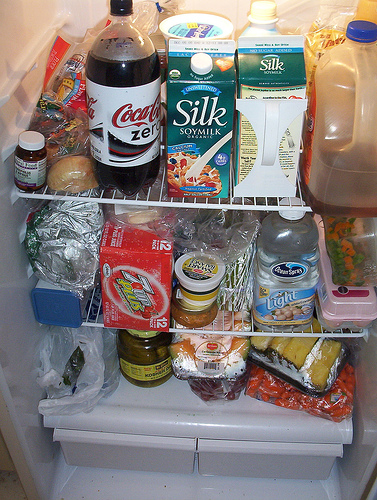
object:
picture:
[1, 0, 377, 497]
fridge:
[1, 0, 375, 497]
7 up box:
[95, 212, 176, 337]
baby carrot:
[336, 371, 355, 401]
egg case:
[311, 213, 375, 337]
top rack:
[4, 0, 376, 216]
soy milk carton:
[161, 33, 238, 208]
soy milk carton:
[233, 28, 306, 201]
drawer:
[48, 427, 199, 483]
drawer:
[195, 432, 348, 485]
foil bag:
[20, 195, 104, 299]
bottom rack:
[27, 324, 366, 449]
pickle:
[114, 327, 173, 391]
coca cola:
[82, 0, 164, 197]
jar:
[114, 327, 169, 390]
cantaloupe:
[168, 332, 250, 381]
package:
[169, 331, 254, 378]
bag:
[243, 361, 357, 426]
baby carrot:
[270, 385, 285, 407]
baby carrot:
[256, 388, 274, 405]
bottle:
[11, 127, 50, 197]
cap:
[16, 128, 46, 153]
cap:
[106, 0, 135, 16]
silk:
[172, 90, 233, 131]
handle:
[49, 428, 200, 454]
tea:
[299, 163, 376, 223]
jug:
[298, 16, 376, 221]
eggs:
[312, 216, 376, 332]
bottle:
[247, 196, 322, 333]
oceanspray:
[270, 263, 310, 279]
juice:
[94, 216, 175, 337]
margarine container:
[171, 248, 227, 330]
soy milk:
[179, 127, 225, 140]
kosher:
[144, 366, 166, 378]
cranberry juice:
[249, 272, 318, 329]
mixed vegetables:
[323, 216, 374, 286]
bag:
[320, 214, 377, 289]